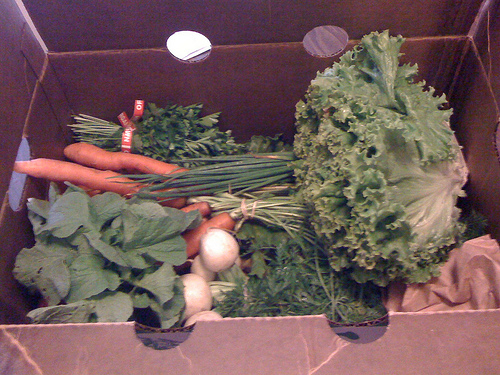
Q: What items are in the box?
A: Vegetables.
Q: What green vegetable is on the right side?
A: Broccoli.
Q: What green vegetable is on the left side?
A: Kale.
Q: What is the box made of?
A: Cardboard.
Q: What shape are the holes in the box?
A: Circle.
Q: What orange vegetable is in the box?
A: Carrots.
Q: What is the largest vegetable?
A: Lettuce.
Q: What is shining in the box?
A: Sunlight.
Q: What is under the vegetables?
A: Brown paper.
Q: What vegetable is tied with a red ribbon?
A: Chives.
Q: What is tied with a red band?
A: Chives.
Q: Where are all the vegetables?
A: In a box.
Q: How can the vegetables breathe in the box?
A: Holes.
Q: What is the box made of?
A: Cardboard.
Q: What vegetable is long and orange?
A: Carrot.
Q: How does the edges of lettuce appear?
A: Curled.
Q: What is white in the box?
A: Mushrooms.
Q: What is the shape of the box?
A: Square.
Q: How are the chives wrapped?
A: In a bundle.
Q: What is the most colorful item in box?
A: Carrots.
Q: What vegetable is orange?
A: The carrots.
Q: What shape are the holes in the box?
A: Circular.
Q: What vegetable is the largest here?
A: The head of romaine lettuce.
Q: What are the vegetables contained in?
A: A cardboard box.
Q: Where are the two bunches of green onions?
A: In the center of the box.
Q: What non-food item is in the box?
A: Crumpled up brown paper.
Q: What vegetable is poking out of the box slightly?
A: A carrot.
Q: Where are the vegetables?
A: A Box.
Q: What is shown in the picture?
A: Vegetables.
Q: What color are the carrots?
A: Orange.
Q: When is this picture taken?
A: At daytime.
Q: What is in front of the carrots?
A: Radishes.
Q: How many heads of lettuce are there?
A: One.